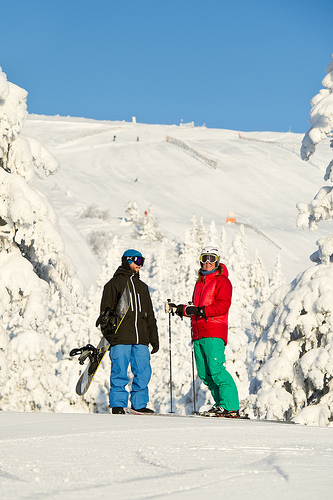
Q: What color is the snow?
A: White.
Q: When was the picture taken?
A: Daytime.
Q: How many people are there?
A: Two.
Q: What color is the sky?
A: Blue.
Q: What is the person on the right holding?
A: Ski poles.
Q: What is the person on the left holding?
A: A snowboard.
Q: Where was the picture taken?
A: In the snow.